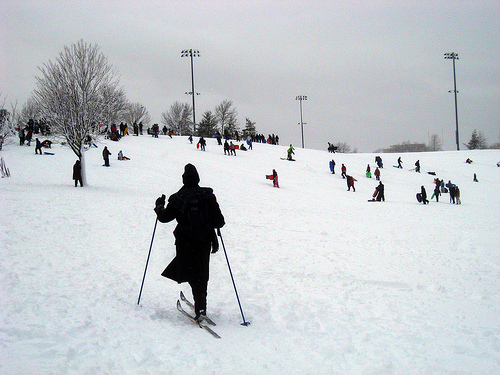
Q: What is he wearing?
A: Skiing shoes.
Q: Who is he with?
A: No one.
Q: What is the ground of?
A: Snow.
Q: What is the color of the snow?
A: White.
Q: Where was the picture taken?
A: In Utah.